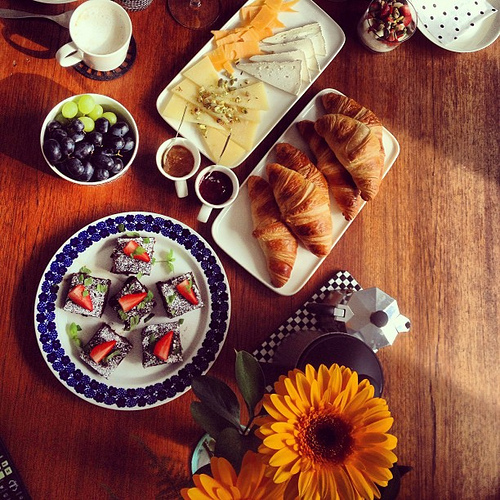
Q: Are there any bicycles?
A: No, there are no bicycles.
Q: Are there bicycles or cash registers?
A: No, there are no bicycles or cash registers.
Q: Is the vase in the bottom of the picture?
A: Yes, the vase is in the bottom of the image.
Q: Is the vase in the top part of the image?
A: No, the vase is in the bottom of the image.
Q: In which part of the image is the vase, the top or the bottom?
A: The vase is in the bottom of the image.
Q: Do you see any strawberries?
A: Yes, there is a strawberry.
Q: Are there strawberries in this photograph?
A: Yes, there is a strawberry.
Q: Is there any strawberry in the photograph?
A: Yes, there is a strawberry.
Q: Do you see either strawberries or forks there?
A: Yes, there is a strawberry.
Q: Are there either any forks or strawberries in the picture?
A: Yes, there is a strawberry.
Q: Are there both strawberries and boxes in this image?
A: No, there is a strawberry but no boxes.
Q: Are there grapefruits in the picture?
A: No, there are no grapefruits.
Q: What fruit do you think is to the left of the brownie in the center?
A: The fruit is a strawberry.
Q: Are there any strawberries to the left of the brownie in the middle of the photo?
A: Yes, there is a strawberry to the left of the bronwy.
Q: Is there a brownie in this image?
A: Yes, there is a brownie.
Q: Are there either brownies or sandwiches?
A: Yes, there is a brownie.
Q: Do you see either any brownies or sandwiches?
A: Yes, there is a brownie.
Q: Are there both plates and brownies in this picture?
A: Yes, there are both a brownie and a plate.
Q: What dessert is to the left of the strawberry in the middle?
A: The dessert is a brownie.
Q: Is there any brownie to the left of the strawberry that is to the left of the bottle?
A: Yes, there is a brownie to the left of the strawberry.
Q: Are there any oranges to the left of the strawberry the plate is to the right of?
A: No, there is a brownie to the left of the strawberry.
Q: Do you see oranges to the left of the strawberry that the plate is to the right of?
A: No, there is a brownie to the left of the strawberry.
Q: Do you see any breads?
A: Yes, there is a bread.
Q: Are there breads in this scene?
A: Yes, there is a bread.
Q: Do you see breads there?
A: Yes, there is a bread.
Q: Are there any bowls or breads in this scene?
A: Yes, there is a bread.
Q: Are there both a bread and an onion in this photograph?
A: No, there is a bread but no onions.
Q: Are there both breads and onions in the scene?
A: No, there is a bread but no onions.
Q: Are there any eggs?
A: No, there are no eggs.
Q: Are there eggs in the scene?
A: No, there are no eggs.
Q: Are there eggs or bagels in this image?
A: No, there are no eggs or bagels.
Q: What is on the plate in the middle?
A: The bread is on the plate.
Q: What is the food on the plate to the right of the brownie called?
A: The food is a bread.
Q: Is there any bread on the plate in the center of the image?
A: Yes, there is a bread on the plate.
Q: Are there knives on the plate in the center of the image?
A: No, there is a bread on the plate.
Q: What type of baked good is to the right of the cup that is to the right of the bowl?
A: The food is a bread.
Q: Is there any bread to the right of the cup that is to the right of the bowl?
A: Yes, there is a bread to the right of the cup.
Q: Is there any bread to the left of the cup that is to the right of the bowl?
A: No, the bread is to the right of the cup.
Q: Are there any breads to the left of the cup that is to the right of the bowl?
A: No, the bread is to the right of the cup.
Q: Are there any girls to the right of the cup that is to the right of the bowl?
A: No, there is a bread to the right of the cup.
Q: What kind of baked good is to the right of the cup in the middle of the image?
A: The food is a bread.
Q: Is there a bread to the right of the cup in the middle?
A: Yes, there is a bread to the right of the cup.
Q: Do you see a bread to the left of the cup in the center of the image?
A: No, the bread is to the right of the cup.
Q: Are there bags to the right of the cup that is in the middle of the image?
A: No, there is a bread to the right of the cup.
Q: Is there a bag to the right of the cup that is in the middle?
A: No, there is a bread to the right of the cup.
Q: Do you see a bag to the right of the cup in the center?
A: No, there is a bread to the right of the cup.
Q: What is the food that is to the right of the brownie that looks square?
A: The food is a bread.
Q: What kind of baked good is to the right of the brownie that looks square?
A: The food is a bread.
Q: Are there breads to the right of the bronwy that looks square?
A: Yes, there is a bread to the right of the bronwy.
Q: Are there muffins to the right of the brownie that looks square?
A: No, there is a bread to the right of the bronwy.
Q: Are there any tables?
A: Yes, there is a table.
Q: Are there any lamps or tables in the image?
A: Yes, there is a table.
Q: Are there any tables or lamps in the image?
A: Yes, there is a table.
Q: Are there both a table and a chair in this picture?
A: No, there is a table but no chairs.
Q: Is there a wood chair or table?
A: Yes, there is a wood table.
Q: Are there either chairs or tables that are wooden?
A: Yes, the table is wooden.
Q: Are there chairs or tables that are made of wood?
A: Yes, the table is made of wood.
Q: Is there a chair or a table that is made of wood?
A: Yes, the table is made of wood.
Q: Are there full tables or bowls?
A: Yes, there is a full table.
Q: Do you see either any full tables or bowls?
A: Yes, there is a full table.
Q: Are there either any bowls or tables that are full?
A: Yes, the table is full.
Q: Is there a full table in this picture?
A: Yes, there is a full table.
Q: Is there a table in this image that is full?
A: Yes, there is a table that is full.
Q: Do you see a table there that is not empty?
A: Yes, there is an full table.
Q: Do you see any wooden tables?
A: Yes, there is a wood table.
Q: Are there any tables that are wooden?
A: Yes, there is a table that is wooden.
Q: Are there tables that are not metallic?
A: Yes, there is a wooden table.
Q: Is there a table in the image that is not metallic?
A: Yes, there is a wooden table.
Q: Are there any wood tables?
A: Yes, there is a table that is made of wood.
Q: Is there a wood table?
A: Yes, there is a table that is made of wood.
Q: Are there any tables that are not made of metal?
A: Yes, there is a table that is made of wood.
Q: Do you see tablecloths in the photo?
A: No, there are no tablecloths.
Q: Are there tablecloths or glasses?
A: No, there are no tablecloths or glasses.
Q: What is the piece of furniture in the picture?
A: The piece of furniture is a table.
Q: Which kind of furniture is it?
A: The piece of furniture is a table.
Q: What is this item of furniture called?
A: This is a table.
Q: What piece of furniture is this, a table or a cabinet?
A: This is a table.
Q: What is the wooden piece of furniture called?
A: The piece of furniture is a table.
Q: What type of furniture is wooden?
A: The furniture is a table.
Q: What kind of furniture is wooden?
A: The furniture is a table.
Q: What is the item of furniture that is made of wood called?
A: The piece of furniture is a table.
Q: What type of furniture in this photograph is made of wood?
A: The furniture is a table.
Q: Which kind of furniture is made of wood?
A: The furniture is a table.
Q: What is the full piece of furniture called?
A: The piece of furniture is a table.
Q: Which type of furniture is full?
A: The furniture is a table.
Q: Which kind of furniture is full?
A: The furniture is a table.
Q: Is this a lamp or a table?
A: This is a table.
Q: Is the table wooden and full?
A: Yes, the table is wooden and full.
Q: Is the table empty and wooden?
A: No, the table is wooden but full.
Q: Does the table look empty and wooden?
A: No, the table is wooden but full.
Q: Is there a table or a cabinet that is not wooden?
A: No, there is a table but it is wooden.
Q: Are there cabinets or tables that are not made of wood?
A: No, there is a table but it is made of wood.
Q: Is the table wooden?
A: Yes, the table is wooden.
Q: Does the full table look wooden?
A: Yes, the table is wooden.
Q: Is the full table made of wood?
A: Yes, the table is made of wood.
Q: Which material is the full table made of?
A: The table is made of wood.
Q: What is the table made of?
A: The table is made of wood.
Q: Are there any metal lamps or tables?
A: No, there is a table but it is wooden.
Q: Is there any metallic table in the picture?
A: No, there is a table but it is wooden.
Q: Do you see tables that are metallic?
A: No, there is a table but it is wooden.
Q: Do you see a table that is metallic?
A: No, there is a table but it is wooden.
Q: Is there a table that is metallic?
A: No, there is a table but it is wooden.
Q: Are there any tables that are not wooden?
A: No, there is a table but it is wooden.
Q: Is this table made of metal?
A: No, the table is made of wood.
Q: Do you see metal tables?
A: No, there is a table but it is made of wood.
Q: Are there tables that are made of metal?
A: No, there is a table but it is made of wood.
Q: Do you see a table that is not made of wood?
A: No, there is a table but it is made of wood.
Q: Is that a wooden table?
A: Yes, that is a wooden table.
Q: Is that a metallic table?
A: No, that is a wooden table.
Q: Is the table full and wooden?
A: Yes, the table is full and wooden.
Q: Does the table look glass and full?
A: No, the table is full but wooden.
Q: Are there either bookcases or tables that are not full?
A: No, there is a table but it is full.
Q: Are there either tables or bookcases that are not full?
A: No, there is a table but it is full.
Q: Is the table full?
A: Yes, the table is full.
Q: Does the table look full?
A: Yes, the table is full.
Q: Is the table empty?
A: No, the table is full.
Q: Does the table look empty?
A: No, the table is full.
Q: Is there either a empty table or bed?
A: No, there is a table but it is full.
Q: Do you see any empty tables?
A: No, there is a table but it is full.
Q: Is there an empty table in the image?
A: No, there is a table but it is full.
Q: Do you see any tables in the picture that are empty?
A: No, there is a table but it is full.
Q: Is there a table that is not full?
A: No, there is a table but it is full.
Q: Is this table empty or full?
A: The table is full.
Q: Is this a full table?
A: Yes, this is a full table.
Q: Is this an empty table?
A: No, this is a full table.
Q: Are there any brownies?
A: Yes, there is a brownie.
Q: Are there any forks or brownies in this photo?
A: Yes, there is a brownie.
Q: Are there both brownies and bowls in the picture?
A: Yes, there are both a brownie and a bowl.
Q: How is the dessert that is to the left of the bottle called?
A: The dessert is a brownie.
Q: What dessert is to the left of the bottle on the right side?
A: The dessert is a brownie.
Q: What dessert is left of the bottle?
A: The dessert is a brownie.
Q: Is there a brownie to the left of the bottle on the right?
A: Yes, there is a brownie to the left of the bottle.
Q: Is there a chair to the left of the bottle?
A: No, there is a brownie to the left of the bottle.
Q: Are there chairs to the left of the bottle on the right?
A: No, there is a brownie to the left of the bottle.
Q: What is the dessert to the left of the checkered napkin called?
A: The dessert is a brownie.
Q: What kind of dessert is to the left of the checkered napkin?
A: The dessert is a brownie.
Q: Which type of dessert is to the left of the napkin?
A: The dessert is a brownie.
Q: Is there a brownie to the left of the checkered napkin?
A: Yes, there is a brownie to the left of the napkin.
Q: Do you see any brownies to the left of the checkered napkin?
A: Yes, there is a brownie to the left of the napkin.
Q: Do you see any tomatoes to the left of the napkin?
A: No, there is a brownie to the left of the napkin.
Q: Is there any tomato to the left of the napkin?
A: No, there is a brownie to the left of the napkin.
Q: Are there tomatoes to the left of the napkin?
A: No, there is a brownie to the left of the napkin.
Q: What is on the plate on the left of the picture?
A: The brownie is on the plate.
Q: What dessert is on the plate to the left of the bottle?
A: The dessert is a brownie.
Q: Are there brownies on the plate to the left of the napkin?
A: Yes, there is a brownie on the plate.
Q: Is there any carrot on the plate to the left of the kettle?
A: No, there is a brownie on the plate.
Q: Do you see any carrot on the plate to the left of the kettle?
A: No, there is a brownie on the plate.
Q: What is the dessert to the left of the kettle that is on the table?
A: The dessert is a brownie.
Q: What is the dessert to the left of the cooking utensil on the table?
A: The dessert is a brownie.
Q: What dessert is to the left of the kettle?
A: The dessert is a brownie.